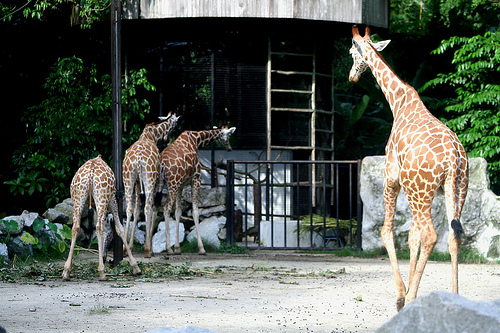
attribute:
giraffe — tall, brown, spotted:
[333, 19, 497, 311]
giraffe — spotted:
[57, 156, 144, 281]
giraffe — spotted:
[349, 24, 461, 308]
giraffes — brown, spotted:
[156, 122, 236, 260]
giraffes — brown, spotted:
[121, 111, 181, 258]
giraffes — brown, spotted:
[58, 150, 143, 282]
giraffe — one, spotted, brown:
[122, 110, 179, 256]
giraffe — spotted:
[155, 122, 235, 254]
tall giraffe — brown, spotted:
[121, 110, 184, 256]